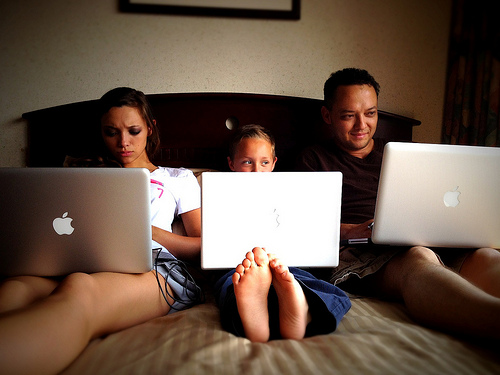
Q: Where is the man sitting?
A: In bed.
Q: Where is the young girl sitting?
A: In bed.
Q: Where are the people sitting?
A: On a bed.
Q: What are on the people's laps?
A: Laptop computers.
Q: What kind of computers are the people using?
A: Apple.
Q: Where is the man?
A: On the right.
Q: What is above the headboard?
A: A frame.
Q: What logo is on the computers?
A: Apple.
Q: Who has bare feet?
A: The girl in the middle.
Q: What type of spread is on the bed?
A: Tan and white striped.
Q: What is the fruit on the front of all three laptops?
A: Apple.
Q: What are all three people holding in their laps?
A: Laptop computers.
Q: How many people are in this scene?
A: Three.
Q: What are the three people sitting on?
A: Bed.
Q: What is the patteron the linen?
A: Stripes.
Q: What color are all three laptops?
A: Silver.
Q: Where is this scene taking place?
A: In a bedroom.